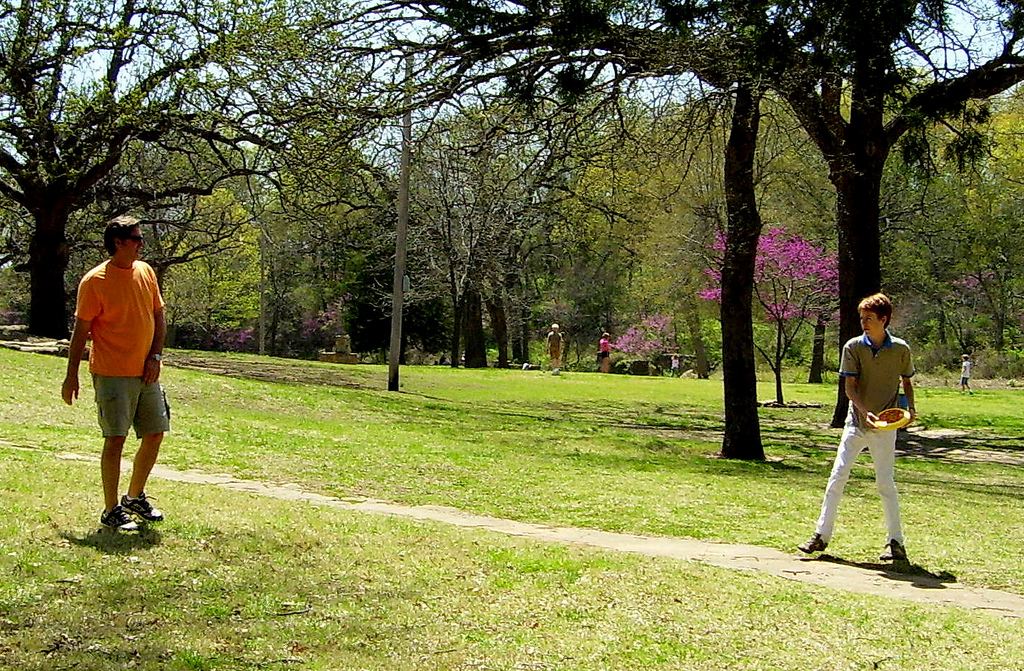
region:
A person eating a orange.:
[631, 394, 740, 500]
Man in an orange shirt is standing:
[74, 258, 164, 379]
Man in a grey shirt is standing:
[841, 337, 912, 429]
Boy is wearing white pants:
[811, 417, 906, 550]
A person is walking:
[542, 319, 566, 374]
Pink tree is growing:
[615, 301, 686, 366]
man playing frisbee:
[69, 192, 181, 537]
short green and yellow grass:
[575, 609, 637, 645]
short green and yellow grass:
[680, 613, 748, 667]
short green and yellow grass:
[358, 514, 425, 572]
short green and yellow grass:
[532, 443, 606, 492]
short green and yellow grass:
[411, 394, 468, 445]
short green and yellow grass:
[614, 499, 701, 548]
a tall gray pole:
[384, 62, 420, 394]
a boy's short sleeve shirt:
[835, 335, 918, 431]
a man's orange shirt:
[76, 256, 172, 386]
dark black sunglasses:
[127, 225, 148, 244]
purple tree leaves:
[691, 230, 840, 332]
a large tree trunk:
[762, 86, 912, 435]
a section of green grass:
[149, 339, 775, 533]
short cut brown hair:
[858, 293, 891, 331]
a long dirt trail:
[86, 452, 1014, 621]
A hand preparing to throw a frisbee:
[877, 410, 907, 424]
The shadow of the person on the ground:
[906, 567, 920, 583]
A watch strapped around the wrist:
[150, 351, 164, 362]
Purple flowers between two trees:
[763, 237, 811, 269]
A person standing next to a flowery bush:
[597, 328, 614, 373]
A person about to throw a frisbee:
[842, 295, 918, 436]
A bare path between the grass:
[663, 539, 703, 553]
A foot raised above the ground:
[802, 540, 826, 553]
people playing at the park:
[93, 113, 989, 546]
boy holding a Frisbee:
[625, 218, 965, 621]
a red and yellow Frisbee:
[701, 199, 1021, 643]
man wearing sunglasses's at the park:
[33, 183, 274, 618]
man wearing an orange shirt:
[22, 186, 232, 509]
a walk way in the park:
[46, 334, 954, 667]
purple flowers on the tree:
[568, 123, 970, 586]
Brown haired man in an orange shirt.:
[57, 213, 174, 533]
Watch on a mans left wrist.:
[148, 349, 162, 366]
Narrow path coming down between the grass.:
[8, 431, 1023, 621]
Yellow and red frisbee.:
[872, 407, 911, 433]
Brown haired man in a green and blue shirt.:
[798, 292, 917, 565]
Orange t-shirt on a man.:
[73, 259, 168, 378]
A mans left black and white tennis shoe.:
[119, 492, 164, 524]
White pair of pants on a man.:
[814, 422, 907, 547]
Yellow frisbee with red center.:
[872, 406, 912, 432]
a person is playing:
[54, 220, 172, 524]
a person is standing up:
[793, 299, 926, 571]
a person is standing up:
[63, 219, 171, 527]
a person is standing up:
[587, 321, 613, 373]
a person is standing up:
[960, 349, 973, 397]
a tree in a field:
[407, 8, 1017, 432]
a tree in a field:
[6, 2, 396, 334]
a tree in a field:
[161, 181, 264, 341]